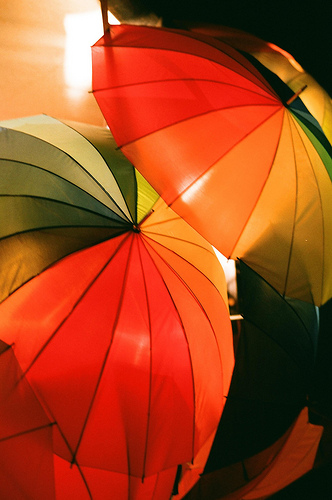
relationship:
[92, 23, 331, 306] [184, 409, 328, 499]
umbrella on a floor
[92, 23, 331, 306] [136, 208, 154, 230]
umbrella has a spine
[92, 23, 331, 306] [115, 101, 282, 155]
umbrella has wires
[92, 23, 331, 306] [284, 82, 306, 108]
umbrella has a connector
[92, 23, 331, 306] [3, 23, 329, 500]
umbrella are in a group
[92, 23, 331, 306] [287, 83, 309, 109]
umbrella has a stick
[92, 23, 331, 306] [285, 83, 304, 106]
umbrella has a top